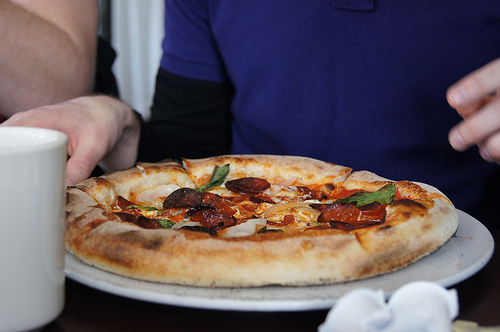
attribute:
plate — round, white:
[432, 249, 469, 276]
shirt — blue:
[164, 1, 442, 139]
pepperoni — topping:
[226, 179, 267, 194]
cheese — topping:
[278, 183, 293, 198]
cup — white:
[3, 125, 67, 330]